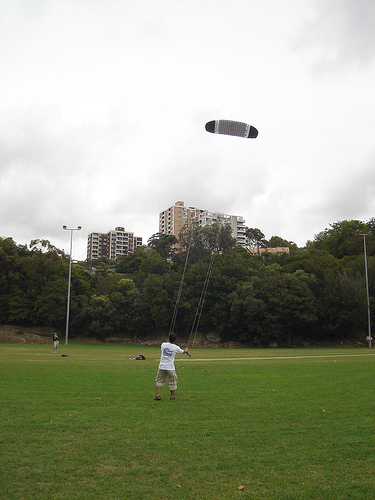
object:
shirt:
[158, 341, 184, 371]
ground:
[0, 342, 375, 498]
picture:
[0, 0, 375, 500]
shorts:
[155, 368, 178, 392]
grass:
[0, 345, 375, 500]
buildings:
[86, 200, 270, 263]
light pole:
[62, 225, 82, 345]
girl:
[52, 331, 60, 353]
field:
[0, 338, 375, 500]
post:
[353, 228, 373, 349]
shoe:
[52, 351, 57, 354]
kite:
[204, 119, 259, 139]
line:
[171, 352, 375, 363]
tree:
[0, 219, 375, 344]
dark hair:
[169, 333, 177, 342]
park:
[0, 322, 375, 498]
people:
[127, 353, 147, 361]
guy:
[154, 332, 189, 400]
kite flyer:
[155, 331, 190, 402]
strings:
[165, 152, 241, 344]